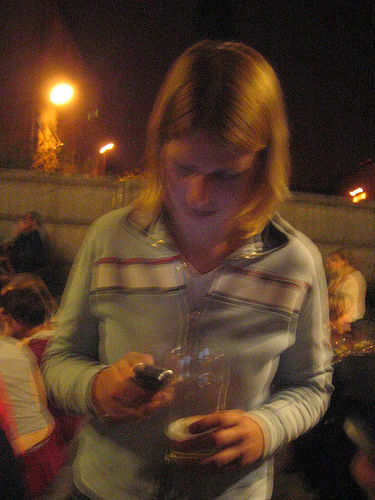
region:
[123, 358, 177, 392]
silver and black cell phone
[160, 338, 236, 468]
nearly empty glass of beer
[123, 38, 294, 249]
shoulder length blonde hair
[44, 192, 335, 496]
light blue collared shirt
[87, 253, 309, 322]
red, white, and blue stripes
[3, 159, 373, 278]
tall wooden fence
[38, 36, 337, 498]
person using a cell phone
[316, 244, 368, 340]
person wearing white walking behind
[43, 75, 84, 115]
bright yellow street light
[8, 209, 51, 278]
guy walking behind in black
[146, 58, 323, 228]
girl has brown hair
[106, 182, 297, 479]
girl has blue shirt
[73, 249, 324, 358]
white stripe on shirt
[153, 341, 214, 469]
girl is holding glass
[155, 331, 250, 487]
small amount of beer in glass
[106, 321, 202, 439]
girl is holding phone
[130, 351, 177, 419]
cell phone is silver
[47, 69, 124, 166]
yellow lights behind girl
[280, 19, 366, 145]
sky is pitch black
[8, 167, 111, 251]
grey wall behind woman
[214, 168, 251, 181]
a blonde woman's left eye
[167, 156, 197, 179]
a blonde woman's right eye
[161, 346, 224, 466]
a blonde woman's glass of beer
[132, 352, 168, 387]
a blonde woman's cellphone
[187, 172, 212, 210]
a blonde woman's nose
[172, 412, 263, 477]
a blonde woman's left hand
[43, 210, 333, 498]
a blonde woman's light blue shirt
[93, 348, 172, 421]
a blonde woman's right hand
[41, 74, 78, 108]
a bright spotlight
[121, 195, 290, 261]
a blonde woman's shirt collar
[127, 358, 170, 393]
cell phone in the girl's hand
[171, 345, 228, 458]
glass of beer in the girl's hand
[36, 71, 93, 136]
street light behind the fence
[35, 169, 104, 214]
fence behind the girl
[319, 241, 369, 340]
person wearing a white shirt behind the girl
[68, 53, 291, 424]
girl looking down at her phone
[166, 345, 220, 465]
glass with a small amount of liquid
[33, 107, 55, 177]
tree behind the fence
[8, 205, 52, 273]
person sitting by the fence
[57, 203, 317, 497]
girl wearing a zip up jacket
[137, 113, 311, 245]
the head of a woman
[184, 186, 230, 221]
the nose of a woman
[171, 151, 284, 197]
the eyes of a woman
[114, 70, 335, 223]
the hair of a woamn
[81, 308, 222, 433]
a woman holding a phone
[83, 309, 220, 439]
the hand of a woman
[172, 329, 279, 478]
a woman holding a glass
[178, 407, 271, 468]
the fingers of a woman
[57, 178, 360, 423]
a woman wearing a jacket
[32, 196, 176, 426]
the arm of a woman